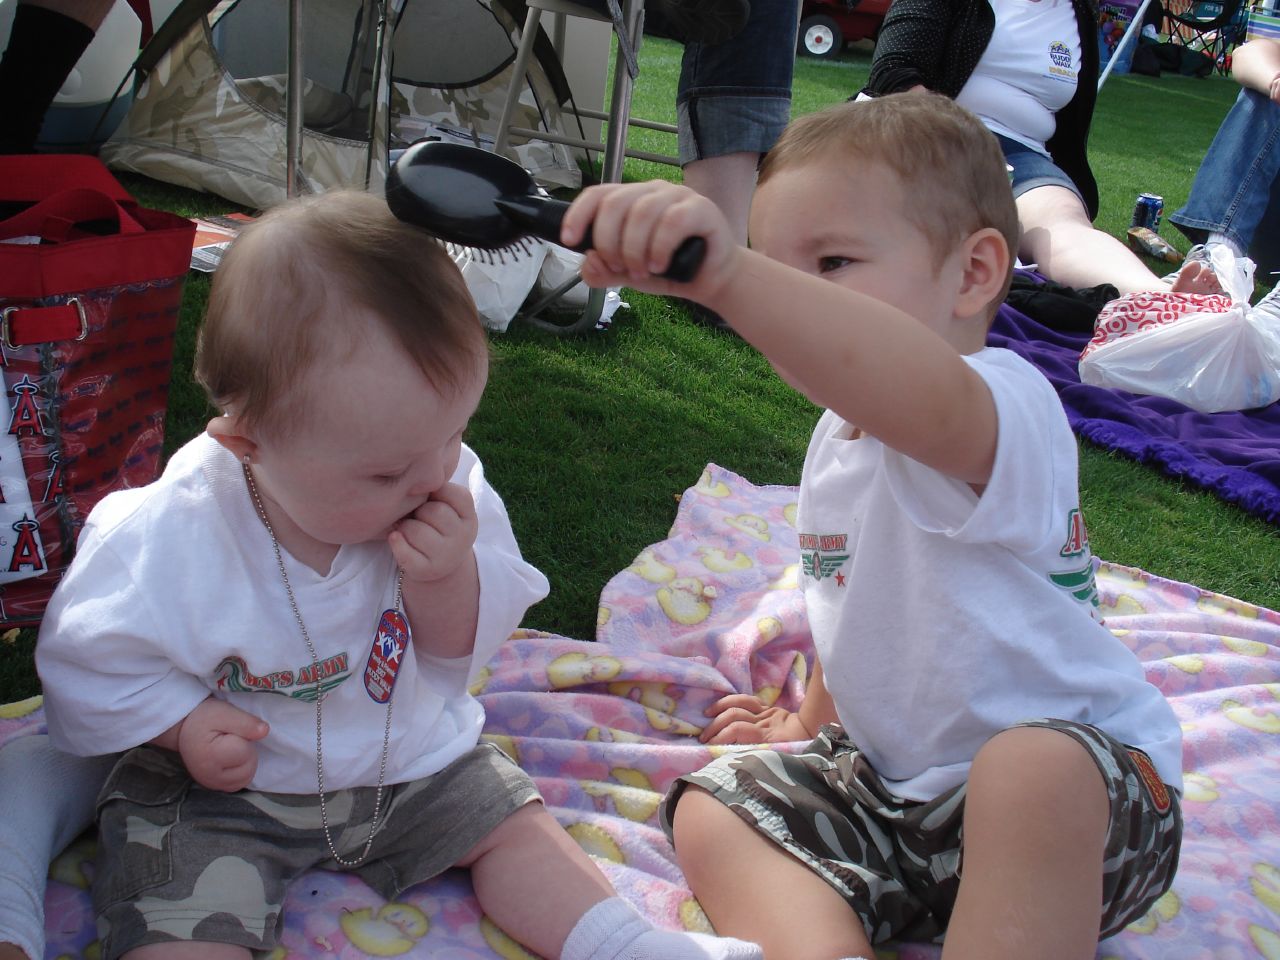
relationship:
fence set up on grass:
[95, 0, 643, 340] [505, 325, 705, 520]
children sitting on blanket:
[17, 56, 1271, 937] [0, 463, 1279, 960]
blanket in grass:
[0, 463, 1279, 960] [505, 341, 656, 552]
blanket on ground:
[986, 264, 1279, 528] [1086, 464, 1267, 589]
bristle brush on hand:
[385, 141, 709, 283] [572, 190, 723, 283]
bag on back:
[0, 159, 190, 652] [44, 420, 195, 566]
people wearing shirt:
[842, 0, 1225, 295] [972, 1, 1072, 138]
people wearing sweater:
[842, 0, 1225, 295] [889, 13, 975, 89]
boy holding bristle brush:
[372, 80, 1238, 952] [385, 141, 709, 283]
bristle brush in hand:
[385, 141, 709, 283] [567, 171, 706, 285]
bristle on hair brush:
[501, 243, 532, 263] [400, 153, 574, 232]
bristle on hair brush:
[483, 248, 506, 265] [402, 162, 578, 236]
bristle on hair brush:
[488, 250, 511, 275] [388, 148, 553, 236]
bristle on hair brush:
[427, 234, 544, 265] [328, 117, 709, 338]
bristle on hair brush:
[486, 247, 498, 272] [380, 126, 710, 286]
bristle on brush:
[463, 252, 518, 282] [379, 96, 681, 354]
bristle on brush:
[427, 234, 544, 265] [328, 84, 677, 340]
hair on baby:
[196, 190, 491, 452] [28, 183, 758, 959]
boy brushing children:
[558, 90, 1185, 960] [25, 85, 1181, 960]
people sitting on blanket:
[842, 0, 1225, 295] [987, 267, 1277, 539]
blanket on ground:
[6, 470, 1260, 958] [1, 2, 1278, 956]